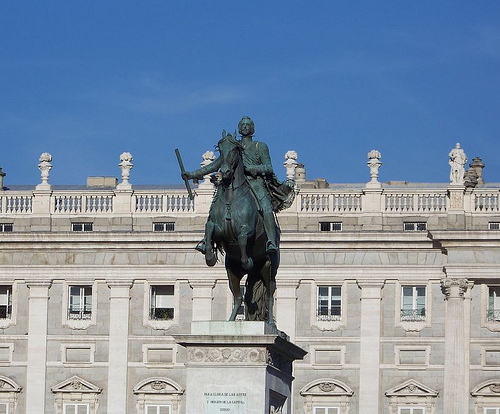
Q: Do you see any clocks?
A: No, there are no clocks.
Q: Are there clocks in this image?
A: No, there are no clocks.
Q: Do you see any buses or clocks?
A: No, there are no clocks or buses.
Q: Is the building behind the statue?
A: Yes, the building is behind the statue.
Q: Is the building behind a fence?
A: No, the building is behind the statue.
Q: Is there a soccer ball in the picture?
A: No, there are no soccer balls.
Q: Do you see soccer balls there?
A: No, there are no soccer balls.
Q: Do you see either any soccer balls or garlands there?
A: No, there are no soccer balls or garlands.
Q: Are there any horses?
A: Yes, there is a horse.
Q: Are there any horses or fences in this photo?
A: Yes, there is a horse.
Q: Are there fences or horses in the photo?
A: Yes, there is a horse.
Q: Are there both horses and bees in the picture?
A: No, there is a horse but no bees.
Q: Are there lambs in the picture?
A: No, there are no lambs.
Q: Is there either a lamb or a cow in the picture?
A: No, there are no lambs or cows.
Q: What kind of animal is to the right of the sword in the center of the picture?
A: The animal is a horse.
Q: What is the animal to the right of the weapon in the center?
A: The animal is a horse.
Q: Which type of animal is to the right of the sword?
A: The animal is a horse.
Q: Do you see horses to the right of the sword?
A: Yes, there is a horse to the right of the sword.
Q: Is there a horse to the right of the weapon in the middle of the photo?
A: Yes, there is a horse to the right of the sword.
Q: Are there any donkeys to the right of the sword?
A: No, there is a horse to the right of the sword.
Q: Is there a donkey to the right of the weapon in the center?
A: No, there is a horse to the right of the sword.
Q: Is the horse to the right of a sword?
A: Yes, the horse is to the right of a sword.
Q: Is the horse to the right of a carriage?
A: No, the horse is to the right of a sword.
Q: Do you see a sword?
A: Yes, there is a sword.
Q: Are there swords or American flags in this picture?
A: Yes, there is a sword.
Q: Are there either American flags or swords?
A: Yes, there is a sword.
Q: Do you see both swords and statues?
A: Yes, there are both a sword and a statue.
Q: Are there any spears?
A: No, there are no spears.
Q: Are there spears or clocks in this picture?
A: No, there are no spears or clocks.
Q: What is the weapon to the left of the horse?
A: The weapon is a sword.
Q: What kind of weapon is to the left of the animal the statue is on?
A: The weapon is a sword.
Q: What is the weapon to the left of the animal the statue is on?
A: The weapon is a sword.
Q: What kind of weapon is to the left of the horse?
A: The weapon is a sword.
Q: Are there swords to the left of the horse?
A: Yes, there is a sword to the left of the horse.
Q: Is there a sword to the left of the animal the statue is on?
A: Yes, there is a sword to the left of the horse.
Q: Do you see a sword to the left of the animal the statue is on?
A: Yes, there is a sword to the left of the horse.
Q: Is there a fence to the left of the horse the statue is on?
A: No, there is a sword to the left of the horse.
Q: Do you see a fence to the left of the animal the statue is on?
A: No, there is a sword to the left of the horse.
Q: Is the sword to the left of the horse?
A: Yes, the sword is to the left of the horse.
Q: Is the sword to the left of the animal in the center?
A: Yes, the sword is to the left of the horse.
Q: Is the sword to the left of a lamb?
A: No, the sword is to the left of the horse.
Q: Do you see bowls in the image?
A: No, there are no bowls.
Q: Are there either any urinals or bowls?
A: No, there are no bowls or urinals.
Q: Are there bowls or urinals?
A: No, there are no bowls or urinals.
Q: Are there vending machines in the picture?
A: No, there are no vending machines.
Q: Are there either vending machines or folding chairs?
A: No, there are no vending machines or folding chairs.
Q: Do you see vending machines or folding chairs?
A: No, there are no vending machines or folding chairs.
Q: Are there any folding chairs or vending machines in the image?
A: No, there are no vending machines or folding chairs.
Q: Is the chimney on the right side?
A: Yes, the chimney is on the right of the image.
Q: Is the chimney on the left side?
A: No, the chimney is on the right of the image.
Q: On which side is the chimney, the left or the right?
A: The chimney is on the right of the image.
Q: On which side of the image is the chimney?
A: The chimney is on the right of the image.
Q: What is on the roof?
A: The chimney is on the roof.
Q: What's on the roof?
A: The chimney is on the roof.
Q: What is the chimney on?
A: The chimney is on the roof.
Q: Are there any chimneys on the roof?
A: Yes, there is a chimney on the roof.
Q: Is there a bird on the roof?
A: No, there is a chimney on the roof.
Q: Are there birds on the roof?
A: No, there is a chimney on the roof.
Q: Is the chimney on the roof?
A: Yes, the chimney is on the roof.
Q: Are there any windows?
A: Yes, there are windows.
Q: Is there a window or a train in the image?
A: Yes, there are windows.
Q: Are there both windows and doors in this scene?
A: No, there are windows but no doors.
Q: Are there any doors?
A: No, there are no doors.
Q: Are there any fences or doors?
A: No, there are no doors or fences.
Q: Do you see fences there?
A: No, there are no fences.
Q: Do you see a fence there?
A: No, there are no fences.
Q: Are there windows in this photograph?
A: Yes, there is a window.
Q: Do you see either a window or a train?
A: Yes, there is a window.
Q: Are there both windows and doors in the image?
A: No, there is a window but no doors.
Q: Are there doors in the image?
A: No, there are no doors.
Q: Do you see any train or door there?
A: No, there are no doors or trains.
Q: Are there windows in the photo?
A: Yes, there is a window.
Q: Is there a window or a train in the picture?
A: Yes, there is a window.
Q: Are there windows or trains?
A: Yes, there is a window.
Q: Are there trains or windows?
A: Yes, there is a window.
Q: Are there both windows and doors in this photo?
A: No, there is a window but no doors.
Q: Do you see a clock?
A: No, there are no clocks.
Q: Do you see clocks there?
A: No, there are no clocks.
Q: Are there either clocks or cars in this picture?
A: No, there are no clocks or cars.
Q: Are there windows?
A: Yes, there is a window.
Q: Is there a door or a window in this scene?
A: Yes, there is a window.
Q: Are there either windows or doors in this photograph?
A: Yes, there is a window.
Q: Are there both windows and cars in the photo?
A: No, there is a window but no cars.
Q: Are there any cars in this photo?
A: No, there are no cars.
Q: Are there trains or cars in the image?
A: No, there are no cars or trains.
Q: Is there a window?
A: Yes, there is a window.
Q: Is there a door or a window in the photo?
A: Yes, there is a window.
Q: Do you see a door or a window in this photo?
A: Yes, there is a window.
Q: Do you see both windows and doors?
A: No, there is a window but no doors.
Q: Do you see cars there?
A: No, there are no cars.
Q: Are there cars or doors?
A: No, there are no cars or doors.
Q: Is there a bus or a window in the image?
A: Yes, there is a window.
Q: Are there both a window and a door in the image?
A: No, there is a window but no doors.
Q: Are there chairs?
A: No, there are no chairs.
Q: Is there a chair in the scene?
A: No, there are no chairs.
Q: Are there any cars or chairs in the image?
A: No, there are no chairs or cars.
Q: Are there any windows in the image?
A: Yes, there is a window.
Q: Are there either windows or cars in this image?
A: Yes, there is a window.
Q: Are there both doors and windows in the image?
A: No, there is a window but no doors.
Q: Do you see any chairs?
A: No, there are no chairs.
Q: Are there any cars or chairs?
A: No, there are no chairs or cars.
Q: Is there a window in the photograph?
A: Yes, there is a window.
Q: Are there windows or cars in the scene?
A: Yes, there is a window.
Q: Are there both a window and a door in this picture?
A: No, there is a window but no doors.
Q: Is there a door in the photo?
A: No, there are no doors.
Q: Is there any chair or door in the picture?
A: No, there are no doors or chairs.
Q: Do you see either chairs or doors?
A: No, there are no doors or chairs.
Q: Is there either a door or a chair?
A: No, there are no doors or chairs.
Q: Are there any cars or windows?
A: Yes, there is a window.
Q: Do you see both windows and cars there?
A: No, there is a window but no cars.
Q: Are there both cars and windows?
A: No, there is a window but no cars.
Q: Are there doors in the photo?
A: No, there are no doors.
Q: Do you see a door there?
A: No, there are no doors.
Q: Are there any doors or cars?
A: No, there are no doors or cars.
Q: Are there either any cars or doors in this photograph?
A: No, there are no doors or cars.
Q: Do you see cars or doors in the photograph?
A: No, there are no doors or cars.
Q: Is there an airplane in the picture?
A: No, there are no airplanes.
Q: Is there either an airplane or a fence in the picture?
A: No, there are no airplanes or fences.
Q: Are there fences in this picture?
A: No, there are no fences.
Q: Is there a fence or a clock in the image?
A: No, there are no fences or clocks.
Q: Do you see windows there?
A: Yes, there is a window.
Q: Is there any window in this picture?
A: Yes, there is a window.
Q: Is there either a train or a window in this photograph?
A: Yes, there is a window.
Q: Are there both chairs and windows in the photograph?
A: No, there is a window but no chairs.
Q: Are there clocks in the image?
A: No, there are no clocks.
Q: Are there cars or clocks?
A: No, there are no clocks or cars.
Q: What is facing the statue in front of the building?
A: The window is facing the statue.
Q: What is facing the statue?
A: The window is facing the statue.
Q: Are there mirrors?
A: No, there are no mirrors.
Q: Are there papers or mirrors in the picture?
A: No, there are no mirrors or papers.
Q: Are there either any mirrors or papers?
A: No, there are no mirrors or papers.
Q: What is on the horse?
A: The statue is on the horse.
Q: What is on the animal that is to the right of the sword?
A: The statue is on the horse.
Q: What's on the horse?
A: The statue is on the horse.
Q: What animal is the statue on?
A: The statue is on the horse.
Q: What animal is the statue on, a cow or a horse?
A: The statue is on a horse.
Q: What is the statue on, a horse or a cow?
A: The statue is on a horse.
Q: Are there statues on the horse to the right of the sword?
A: Yes, there is a statue on the horse.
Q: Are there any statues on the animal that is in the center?
A: Yes, there is a statue on the horse.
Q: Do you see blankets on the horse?
A: No, there is a statue on the horse.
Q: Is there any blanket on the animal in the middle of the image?
A: No, there is a statue on the horse.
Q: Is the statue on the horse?
A: Yes, the statue is on the horse.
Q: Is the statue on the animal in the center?
A: Yes, the statue is on the horse.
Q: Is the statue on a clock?
A: No, the statue is on the horse.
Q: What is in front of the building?
A: The statue is in front of the building.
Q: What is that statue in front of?
A: The statue is in front of the building.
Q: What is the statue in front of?
A: The statue is in front of the building.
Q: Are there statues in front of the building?
A: Yes, there is a statue in front of the building.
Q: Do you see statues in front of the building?
A: Yes, there is a statue in front of the building.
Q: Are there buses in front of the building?
A: No, there is a statue in front of the building.